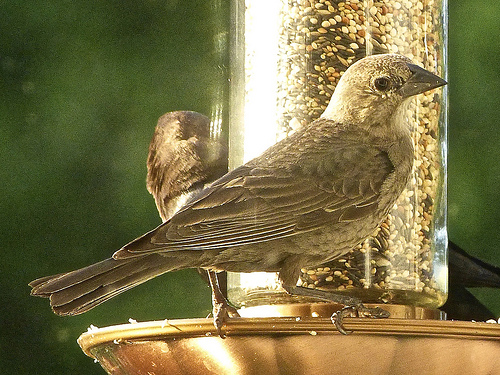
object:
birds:
[145, 110, 238, 341]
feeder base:
[76, 315, 497, 374]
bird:
[26, 51, 449, 338]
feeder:
[76, 1, 499, 374]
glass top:
[224, 0, 449, 305]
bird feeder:
[75, 0, 498, 373]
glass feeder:
[224, 0, 449, 309]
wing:
[110, 122, 389, 263]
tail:
[22, 255, 184, 317]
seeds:
[280, 0, 444, 304]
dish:
[75, 314, 498, 374]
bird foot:
[329, 298, 388, 338]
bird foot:
[207, 301, 242, 340]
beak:
[398, 63, 449, 99]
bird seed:
[279, 0, 444, 302]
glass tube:
[222, 0, 447, 305]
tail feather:
[17, 246, 185, 322]